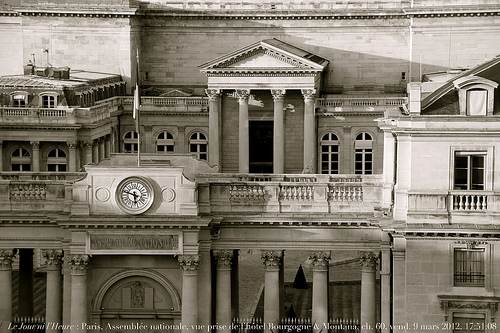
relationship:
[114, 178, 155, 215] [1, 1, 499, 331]
clock on building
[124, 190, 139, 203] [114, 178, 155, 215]
hand on clock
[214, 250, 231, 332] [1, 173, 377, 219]
column holding balcony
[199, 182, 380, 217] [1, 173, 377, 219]
rail on balcony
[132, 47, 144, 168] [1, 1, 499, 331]
flag on building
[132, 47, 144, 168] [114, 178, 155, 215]
flag above clock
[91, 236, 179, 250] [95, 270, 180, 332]
carving above doorway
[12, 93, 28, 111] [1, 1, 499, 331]
window on building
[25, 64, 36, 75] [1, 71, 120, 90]
bucket on roof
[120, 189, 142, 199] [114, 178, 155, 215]
hand on clock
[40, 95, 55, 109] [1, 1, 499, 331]
window on building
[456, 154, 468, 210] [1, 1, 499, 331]
window on building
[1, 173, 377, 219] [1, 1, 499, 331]
balcony on building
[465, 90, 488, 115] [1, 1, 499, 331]
window on building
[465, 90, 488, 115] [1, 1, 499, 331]
window on top of building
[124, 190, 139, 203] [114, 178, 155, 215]
hand of clock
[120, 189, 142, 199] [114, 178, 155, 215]
hand of clock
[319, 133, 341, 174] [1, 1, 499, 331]
window on building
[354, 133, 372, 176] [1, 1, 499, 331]
window on building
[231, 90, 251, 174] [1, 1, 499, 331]
column on building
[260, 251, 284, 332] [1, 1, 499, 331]
column on building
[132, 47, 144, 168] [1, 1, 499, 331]
flag on top of building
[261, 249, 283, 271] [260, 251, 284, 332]
decoration on top of column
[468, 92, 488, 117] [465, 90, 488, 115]
curtain covering window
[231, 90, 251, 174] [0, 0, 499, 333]
pillar on building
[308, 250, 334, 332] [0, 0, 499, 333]
pillar on building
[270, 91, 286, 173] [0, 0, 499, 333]
pillar on building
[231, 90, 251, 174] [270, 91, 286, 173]
pillar next to pillar